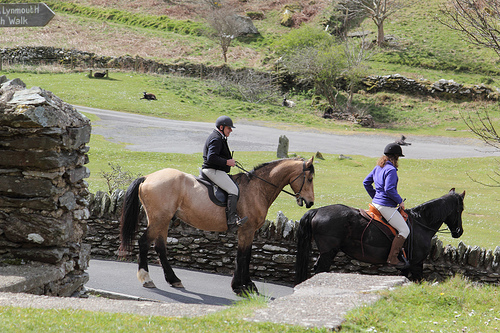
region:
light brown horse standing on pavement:
[121, 155, 323, 283]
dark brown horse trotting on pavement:
[283, 179, 468, 289]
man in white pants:
[201, 167, 246, 199]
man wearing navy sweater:
[198, 131, 232, 168]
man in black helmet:
[216, 115, 236, 135]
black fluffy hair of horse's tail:
[118, 177, 148, 247]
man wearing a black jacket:
[198, 122, 248, 172]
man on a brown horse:
[188, 105, 249, 243]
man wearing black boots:
[220, 190, 251, 235]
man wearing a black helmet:
[214, 111, 235, 131]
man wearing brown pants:
[200, 161, 237, 196]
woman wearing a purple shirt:
[366, 160, 408, 203]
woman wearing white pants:
[369, 198, 411, 240]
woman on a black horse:
[351, 133, 445, 277]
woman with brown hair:
[376, 142, 398, 167]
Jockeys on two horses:
[127, 145, 459, 262]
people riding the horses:
[111, 110, 471, 302]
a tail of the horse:
[112, 171, 154, 258]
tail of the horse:
[287, 205, 323, 282]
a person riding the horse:
[197, 112, 254, 234]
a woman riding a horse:
[359, 140, 419, 268]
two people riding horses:
[113, 112, 473, 298]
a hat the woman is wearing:
[381, 140, 407, 160]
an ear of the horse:
[458, 187, 468, 197]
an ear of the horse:
[446, 183, 458, 192]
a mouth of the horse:
[295, 193, 314, 210]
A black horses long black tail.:
[297, 209, 318, 283]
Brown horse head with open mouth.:
[288, 154, 315, 206]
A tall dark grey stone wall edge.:
[1, 74, 89, 300]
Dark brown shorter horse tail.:
[118, 174, 145, 249]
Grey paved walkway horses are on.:
[81, 255, 293, 309]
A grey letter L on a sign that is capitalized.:
[1, 4, 7, 15]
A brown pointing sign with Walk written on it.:
[0, 2, 54, 28]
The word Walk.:
[5, 14, 27, 25]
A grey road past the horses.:
[67, 100, 497, 160]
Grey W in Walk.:
[5, 15, 16, 26]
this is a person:
[366, 142, 418, 270]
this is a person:
[194, 107, 246, 239]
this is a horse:
[295, 189, 469, 276]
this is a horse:
[115, 158, 320, 295]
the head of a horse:
[275, 147, 323, 210]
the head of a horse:
[437, 188, 469, 242]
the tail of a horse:
[115, 173, 143, 255]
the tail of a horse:
[287, 204, 323, 288]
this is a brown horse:
[120, 157, 317, 294]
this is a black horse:
[296, 190, 470, 282]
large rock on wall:
[17, 86, 59, 143]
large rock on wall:
[37, 141, 87, 172]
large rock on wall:
[69, 172, 86, 207]